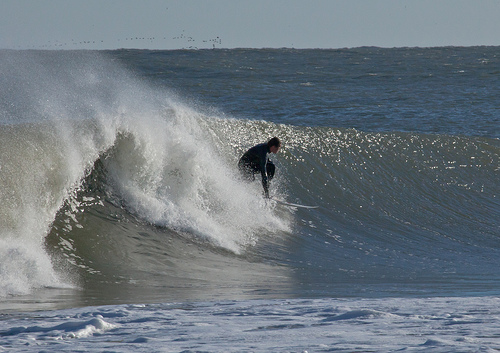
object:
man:
[237, 136, 280, 199]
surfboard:
[271, 193, 321, 212]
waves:
[0, 117, 500, 353]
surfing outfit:
[238, 144, 271, 197]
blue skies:
[0, 0, 500, 50]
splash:
[0, 48, 228, 127]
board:
[264, 196, 320, 208]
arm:
[260, 156, 270, 195]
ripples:
[0, 134, 500, 353]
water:
[0, 45, 500, 352]